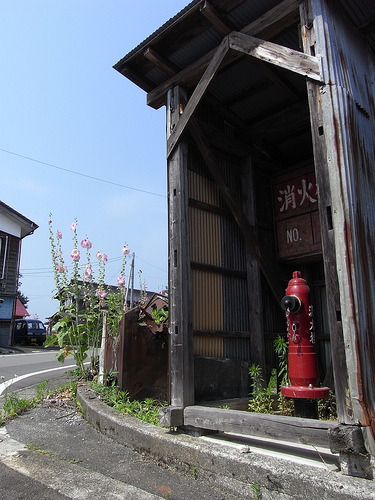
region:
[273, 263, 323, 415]
The fire hydrant is red.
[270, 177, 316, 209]
The lettering is white.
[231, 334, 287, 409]
The weeks are next to the hydrant.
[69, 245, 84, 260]
The flower is pink.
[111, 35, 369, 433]
The building is old.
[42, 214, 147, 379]
The flowers are growing next to the building.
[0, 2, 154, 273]
The sky is blue.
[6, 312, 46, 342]
The car is blue.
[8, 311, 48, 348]
The car is parked next to the building.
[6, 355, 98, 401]
The paint is white.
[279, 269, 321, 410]
Tall red fire hydrant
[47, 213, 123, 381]
A bunch of weeds and pink flowers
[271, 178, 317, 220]
Chinese writing on wall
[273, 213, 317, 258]
No written on wall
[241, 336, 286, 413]
Small set of weeds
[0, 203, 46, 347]
Half of a house and blue car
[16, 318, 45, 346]
Blue car in a driveway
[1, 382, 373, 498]
Street with white lines and curb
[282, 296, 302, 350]
Black knob and chain on firehydrant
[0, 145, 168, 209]
Single power line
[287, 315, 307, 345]
a heavy silver chain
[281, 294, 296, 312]
a black nozzle on the hydrant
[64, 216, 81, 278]
tall pink flowers on a stalk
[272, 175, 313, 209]
Asian writing above the door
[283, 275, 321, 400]
a red fir hydrant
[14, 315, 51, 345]
a blue van is parked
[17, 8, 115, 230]
a clear blue sky overhead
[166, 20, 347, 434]
a small wooden shack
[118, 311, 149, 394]
a rusty brown fence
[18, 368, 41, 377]
a white line on thee street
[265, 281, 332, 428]
A red fire hydrant in a wooden building.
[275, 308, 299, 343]
Chain hanging from the fie hydrant.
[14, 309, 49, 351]
A van parked next to the building.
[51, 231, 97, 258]
Purple flowers on the tree.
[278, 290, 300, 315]
The valve is black.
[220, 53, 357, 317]
The building is wooden.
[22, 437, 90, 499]
White line on the edge of sidewalk.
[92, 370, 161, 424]
Green grass growing by the wooden old building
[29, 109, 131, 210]
The sky is clear.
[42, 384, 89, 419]
Rocks on the ground